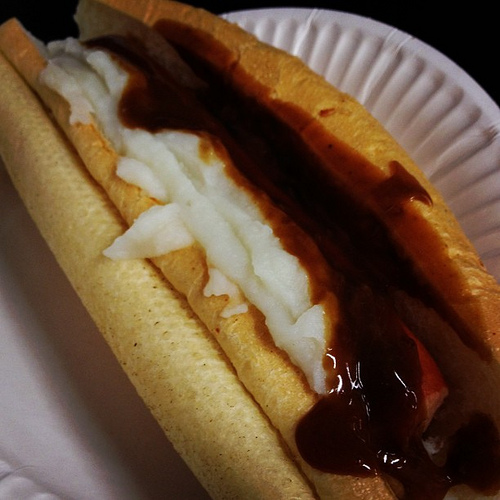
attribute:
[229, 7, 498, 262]
plate — paper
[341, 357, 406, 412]
sauce — ketchup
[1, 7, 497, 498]
plate — paper, white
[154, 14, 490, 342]
sauce — brown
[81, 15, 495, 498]
sauce — brown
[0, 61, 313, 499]
spots — brown